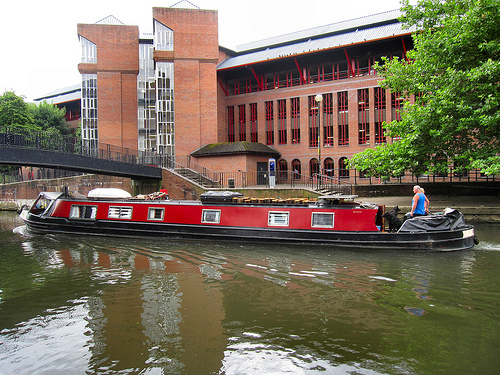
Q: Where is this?
A: This is at the lake.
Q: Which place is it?
A: It is a lake.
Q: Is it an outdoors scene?
A: Yes, it is outdoors.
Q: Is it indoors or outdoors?
A: It is outdoors.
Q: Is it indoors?
A: No, it is outdoors.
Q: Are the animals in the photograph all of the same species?
A: Yes, all the animals are dogs.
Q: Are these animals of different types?
A: No, all the animals are dogs.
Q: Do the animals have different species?
A: No, all the animals are dogs.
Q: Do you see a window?
A: Yes, there is a window.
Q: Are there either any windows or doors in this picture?
A: Yes, there is a window.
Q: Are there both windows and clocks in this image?
A: No, there is a window but no clocks.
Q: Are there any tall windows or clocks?
A: Yes, there is a tall window.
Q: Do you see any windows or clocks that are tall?
A: Yes, the window is tall.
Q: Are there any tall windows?
A: Yes, there is a tall window.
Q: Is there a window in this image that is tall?
A: Yes, there is a tall window.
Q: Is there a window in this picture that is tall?
A: Yes, there is a window that is tall.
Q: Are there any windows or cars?
A: Yes, there is a window.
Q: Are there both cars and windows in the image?
A: No, there is a window but no cars.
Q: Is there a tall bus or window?
A: Yes, there is a tall window.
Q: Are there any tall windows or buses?
A: Yes, there is a tall window.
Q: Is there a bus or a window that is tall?
A: Yes, the window is tall.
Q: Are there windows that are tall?
A: Yes, there is a window that is tall.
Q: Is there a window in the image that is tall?
A: Yes, there is a window that is tall.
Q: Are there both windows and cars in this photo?
A: No, there is a window but no cars.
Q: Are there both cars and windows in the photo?
A: No, there is a window but no cars.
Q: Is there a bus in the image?
A: No, there are no buses.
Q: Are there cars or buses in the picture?
A: No, there are no buses or cars.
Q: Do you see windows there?
A: Yes, there is a window.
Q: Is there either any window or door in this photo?
A: Yes, there is a window.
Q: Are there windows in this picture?
A: Yes, there is a window.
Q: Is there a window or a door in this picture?
A: Yes, there is a window.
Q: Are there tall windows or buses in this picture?
A: Yes, there is a tall window.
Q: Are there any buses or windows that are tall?
A: Yes, the window is tall.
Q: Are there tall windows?
A: Yes, there is a tall window.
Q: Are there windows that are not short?
A: Yes, there is a tall window.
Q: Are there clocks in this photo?
A: No, there are no clocks.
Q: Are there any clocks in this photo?
A: No, there are no clocks.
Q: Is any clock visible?
A: No, there are no clocks.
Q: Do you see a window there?
A: Yes, there is a window.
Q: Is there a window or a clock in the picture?
A: Yes, there is a window.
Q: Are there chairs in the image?
A: No, there are no chairs.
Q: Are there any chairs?
A: No, there are no chairs.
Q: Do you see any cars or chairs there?
A: No, there are no chairs or cars.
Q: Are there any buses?
A: No, there are no buses.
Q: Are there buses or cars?
A: No, there are no buses or cars.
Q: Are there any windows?
A: Yes, there is a window.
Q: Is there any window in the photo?
A: Yes, there is a window.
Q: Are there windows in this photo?
A: Yes, there is a window.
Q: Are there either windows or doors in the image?
A: Yes, there is a window.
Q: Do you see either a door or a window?
A: Yes, there is a window.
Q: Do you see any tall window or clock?
A: Yes, there is a tall window.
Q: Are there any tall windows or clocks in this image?
A: Yes, there is a tall window.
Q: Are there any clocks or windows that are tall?
A: Yes, the window is tall.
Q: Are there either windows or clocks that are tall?
A: Yes, the window is tall.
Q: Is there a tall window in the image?
A: Yes, there is a tall window.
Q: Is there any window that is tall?
A: Yes, there is a window that is tall.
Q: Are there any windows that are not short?
A: Yes, there is a tall window.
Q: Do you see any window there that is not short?
A: Yes, there is a tall window.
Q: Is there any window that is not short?
A: Yes, there is a tall window.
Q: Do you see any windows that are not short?
A: Yes, there is a tall window.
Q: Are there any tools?
A: No, there are no tools.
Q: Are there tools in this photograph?
A: No, there are no tools.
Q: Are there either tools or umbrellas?
A: No, there are no tools or umbrellas.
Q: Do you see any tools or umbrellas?
A: No, there are no tools or umbrellas.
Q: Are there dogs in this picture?
A: Yes, there is a dog.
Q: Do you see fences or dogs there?
A: Yes, there is a dog.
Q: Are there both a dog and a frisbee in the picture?
A: No, there is a dog but no frisbees.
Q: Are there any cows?
A: No, there are no cows.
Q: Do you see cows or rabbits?
A: No, there are no cows or rabbits.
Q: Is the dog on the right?
A: Yes, the dog is on the right of the image.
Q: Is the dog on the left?
A: No, the dog is on the right of the image.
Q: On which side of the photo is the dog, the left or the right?
A: The dog is on the right of the image.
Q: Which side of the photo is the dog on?
A: The dog is on the right of the image.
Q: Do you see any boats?
A: Yes, there is a boat.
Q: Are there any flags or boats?
A: Yes, there is a boat.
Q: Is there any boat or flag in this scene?
A: Yes, there is a boat.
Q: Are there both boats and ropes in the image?
A: No, there is a boat but no ropes.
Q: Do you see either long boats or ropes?
A: Yes, there is a long boat.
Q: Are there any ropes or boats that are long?
A: Yes, the boat is long.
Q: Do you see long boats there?
A: Yes, there is a long boat.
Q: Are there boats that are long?
A: Yes, there is a boat that is long.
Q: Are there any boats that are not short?
A: Yes, there is a long boat.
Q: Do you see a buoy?
A: No, there are no buoys.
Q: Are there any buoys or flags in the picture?
A: No, there are no buoys or flags.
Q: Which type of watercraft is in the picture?
A: The watercraft is a boat.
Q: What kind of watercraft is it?
A: The watercraft is a boat.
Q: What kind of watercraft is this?
A: This is a boat.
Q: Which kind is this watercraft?
A: This is a boat.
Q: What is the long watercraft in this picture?
A: The watercraft is a boat.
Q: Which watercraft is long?
A: The watercraft is a boat.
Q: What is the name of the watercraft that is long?
A: The watercraft is a boat.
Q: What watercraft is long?
A: The watercraft is a boat.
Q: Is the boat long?
A: Yes, the boat is long.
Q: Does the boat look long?
A: Yes, the boat is long.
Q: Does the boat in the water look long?
A: Yes, the boat is long.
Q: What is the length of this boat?
A: The boat is long.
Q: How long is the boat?
A: The boat is long.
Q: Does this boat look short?
A: No, the boat is long.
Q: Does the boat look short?
A: No, the boat is long.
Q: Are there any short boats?
A: No, there is a boat but it is long.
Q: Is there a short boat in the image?
A: No, there is a boat but it is long.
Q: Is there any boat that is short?
A: No, there is a boat but it is long.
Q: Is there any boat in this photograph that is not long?
A: No, there is a boat but it is long.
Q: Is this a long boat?
A: Yes, this is a long boat.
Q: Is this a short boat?
A: No, this is a long boat.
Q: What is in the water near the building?
A: The boat is in the water.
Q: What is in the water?
A: The boat is in the water.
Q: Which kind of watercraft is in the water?
A: The watercraft is a boat.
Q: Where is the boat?
A: The boat is in the water.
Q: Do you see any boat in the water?
A: Yes, there is a boat in the water.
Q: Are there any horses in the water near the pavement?
A: No, there is a boat in the water.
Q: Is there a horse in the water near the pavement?
A: No, there is a boat in the water.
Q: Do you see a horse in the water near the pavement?
A: No, there is a boat in the water.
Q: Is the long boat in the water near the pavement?
A: Yes, the boat is in the water.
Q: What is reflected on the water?
A: The boat is reflected on the water.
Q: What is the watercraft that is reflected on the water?
A: The watercraft is a boat.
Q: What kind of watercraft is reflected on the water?
A: The watercraft is a boat.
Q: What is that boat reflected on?
A: The boat is reflected on the water.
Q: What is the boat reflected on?
A: The boat is reflected on the water.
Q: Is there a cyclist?
A: No, there are no cyclists.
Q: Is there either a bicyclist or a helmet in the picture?
A: No, there are no cyclists or helmets.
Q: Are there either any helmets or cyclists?
A: No, there are no cyclists or helmets.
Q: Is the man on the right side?
A: Yes, the man is on the right of the image.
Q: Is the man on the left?
A: No, the man is on the right of the image.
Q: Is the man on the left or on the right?
A: The man is on the right of the image.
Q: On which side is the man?
A: The man is on the right of the image.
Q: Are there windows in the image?
A: Yes, there are windows.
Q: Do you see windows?
A: Yes, there are windows.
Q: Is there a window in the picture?
A: Yes, there are windows.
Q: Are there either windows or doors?
A: Yes, there are windows.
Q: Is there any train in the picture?
A: No, there are no trains.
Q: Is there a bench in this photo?
A: No, there are no benches.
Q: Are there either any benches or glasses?
A: No, there are no benches or glasses.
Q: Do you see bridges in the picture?
A: Yes, there is a bridge.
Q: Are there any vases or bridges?
A: Yes, there is a bridge.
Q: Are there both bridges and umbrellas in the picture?
A: No, there is a bridge but no umbrellas.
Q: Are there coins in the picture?
A: No, there are no coins.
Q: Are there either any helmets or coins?
A: No, there are no coins or helmets.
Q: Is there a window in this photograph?
A: Yes, there is a window.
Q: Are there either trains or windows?
A: Yes, there is a window.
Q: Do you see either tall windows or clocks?
A: Yes, there is a tall window.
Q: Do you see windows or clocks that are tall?
A: Yes, the window is tall.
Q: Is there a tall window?
A: Yes, there is a tall window.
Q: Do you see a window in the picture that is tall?
A: Yes, there is a window that is tall.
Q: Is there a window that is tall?
A: Yes, there is a window that is tall.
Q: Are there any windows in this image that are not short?
A: Yes, there is a tall window.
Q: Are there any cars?
A: No, there are no cars.